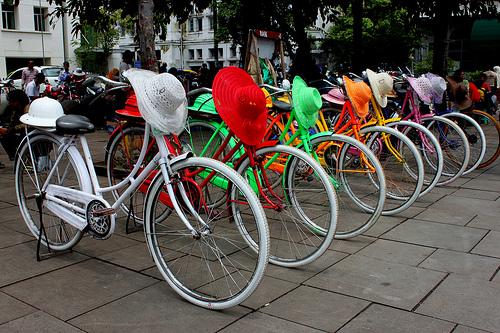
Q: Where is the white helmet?
A: On top of the rear of the bicycle seat.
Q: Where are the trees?
A: Behind the bicycles on the side of the street.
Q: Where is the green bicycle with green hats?
A: It is standing third from the left.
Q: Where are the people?
A: They are on the distance behind the bicycles sitting down.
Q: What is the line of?
A: Bikes.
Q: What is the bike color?
A: White.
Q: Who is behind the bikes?
A: A group of people.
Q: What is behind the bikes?
A: A green tree.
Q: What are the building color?
A: White.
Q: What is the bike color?
A: Yellow.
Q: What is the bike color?
A: Green.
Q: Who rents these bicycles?
A: Tourists.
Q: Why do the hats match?
A: To find the rented bike.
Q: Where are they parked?
A: On the sidewalk.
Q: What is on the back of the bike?
A: A matching pith helmet.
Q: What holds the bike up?
A: The kick stand.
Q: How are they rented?
A: Hourly or daily.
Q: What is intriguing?
A: Hat color matching bicycle color.